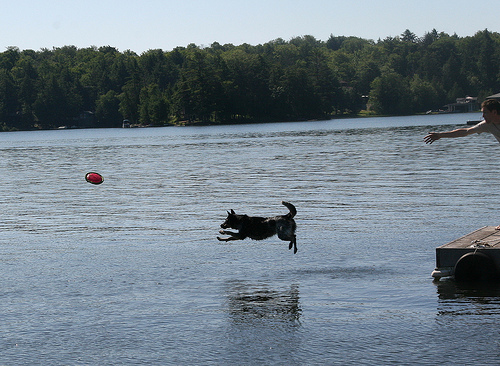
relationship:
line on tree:
[4, 22, 498, 129] [296, 31, 348, 106]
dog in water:
[217, 201, 298, 255] [1, 112, 498, 364]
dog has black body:
[216, 196, 297, 255] [215, 197, 298, 251]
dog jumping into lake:
[217, 201, 298, 255] [154, 136, 495, 213]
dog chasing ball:
[217, 201, 298, 255] [79, 167, 106, 187]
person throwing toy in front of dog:
[423, 91, 499, 148] [216, 200, 298, 252]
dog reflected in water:
[217, 201, 298, 255] [1, 112, 498, 364]